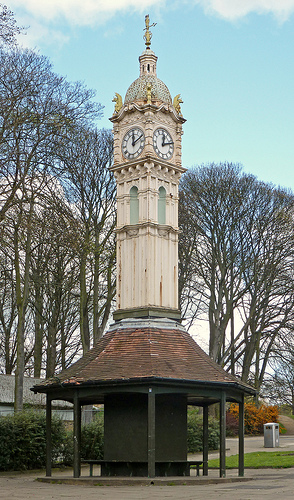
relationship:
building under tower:
[30, 318, 257, 487] [108, 15, 187, 321]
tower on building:
[108, 15, 187, 321] [30, 318, 257, 487]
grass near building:
[191, 452, 293, 468] [30, 318, 257, 487]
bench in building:
[78, 458, 204, 476] [30, 318, 257, 487]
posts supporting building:
[45, 389, 245, 479] [30, 318, 257, 487]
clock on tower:
[121, 128, 147, 160] [108, 15, 187, 321]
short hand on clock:
[130, 132, 136, 146] [121, 128, 147, 160]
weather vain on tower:
[141, 14, 159, 50] [108, 15, 187, 321]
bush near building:
[0, 409, 66, 471] [30, 318, 257, 487]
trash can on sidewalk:
[263, 421, 281, 448] [1, 410, 293, 499]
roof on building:
[30, 317, 259, 394] [30, 318, 257, 487]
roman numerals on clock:
[121, 128, 146, 160] [121, 128, 147, 160]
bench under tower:
[78, 458, 204, 476] [108, 15, 187, 321]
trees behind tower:
[0, 1, 293, 409] [108, 15, 187, 321]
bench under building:
[78, 458, 204, 476] [30, 318, 257, 487]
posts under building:
[45, 389, 245, 479] [30, 318, 257, 487]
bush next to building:
[0, 409, 66, 471] [30, 318, 257, 487]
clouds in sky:
[0, 1, 292, 406] [0, 2, 293, 408]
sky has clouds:
[0, 2, 293, 408] [0, 1, 292, 406]